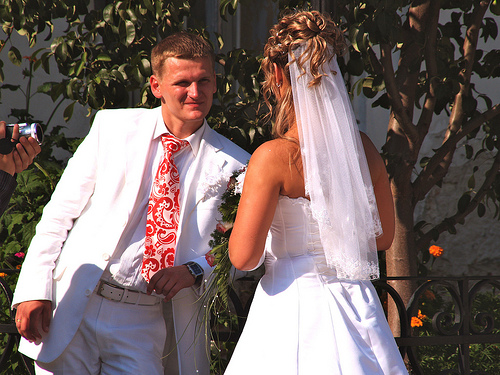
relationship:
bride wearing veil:
[249, 24, 342, 179] [291, 53, 374, 267]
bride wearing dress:
[249, 24, 342, 179] [251, 191, 377, 356]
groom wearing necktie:
[139, 20, 218, 137] [144, 125, 190, 282]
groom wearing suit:
[139, 20, 218, 137] [75, 96, 227, 366]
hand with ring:
[10, 299, 54, 345] [14, 316, 22, 324]